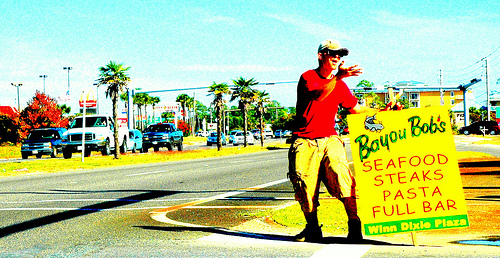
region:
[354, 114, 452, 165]
Green "Bayou Bob's" writing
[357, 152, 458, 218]
Red Seafood, Steaks, Pasta, Full bar writing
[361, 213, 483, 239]
Green and yellow "Winn Dixie Plaza" writing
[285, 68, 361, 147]
Red shirt man is wearing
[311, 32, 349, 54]
Baseball cap man is wearing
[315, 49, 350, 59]
Black sunglasses man is wearing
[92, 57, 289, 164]
Brown and green palm trees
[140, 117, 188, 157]
Blue truck on road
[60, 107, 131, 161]
White truck on road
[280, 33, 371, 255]
Man holding advertising sign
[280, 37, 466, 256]
a man holding a sign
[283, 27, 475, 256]
a man signing to passerbyers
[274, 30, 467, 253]
a man enticing customers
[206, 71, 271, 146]
palm trees behind the man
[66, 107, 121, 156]
a white van driving past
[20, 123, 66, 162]
a black suv driving on the street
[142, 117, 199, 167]
a black pick up truck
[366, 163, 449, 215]
red lettering on a yellow sign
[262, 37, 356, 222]
a man wearing a red shirt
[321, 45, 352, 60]
black sunglasses on a face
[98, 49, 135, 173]
A palm tree.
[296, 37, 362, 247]
A man wearing a red shirt.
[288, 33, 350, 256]
A man wearing a baseball hat.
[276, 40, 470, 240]
A man holding a sign.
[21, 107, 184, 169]
Cars driving on the road.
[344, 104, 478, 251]
A sign for a restaurant.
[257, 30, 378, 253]
A man standing on the road.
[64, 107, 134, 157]
A white pick up truck.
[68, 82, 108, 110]
A McDonald sign.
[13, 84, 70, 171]
A red tree.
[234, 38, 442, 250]
man holding sign on side of street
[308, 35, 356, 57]
brown cap on man's head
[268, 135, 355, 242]
tan cargo shorts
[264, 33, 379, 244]
man making hand gestures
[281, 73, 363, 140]
red t-shirt on man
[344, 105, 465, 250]
red and yellow sign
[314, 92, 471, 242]
lettering on sign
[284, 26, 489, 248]
man holding food sign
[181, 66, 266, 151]
group of palm trees in background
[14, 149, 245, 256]
asphalt road by man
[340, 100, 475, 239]
yellow sign on sidewalk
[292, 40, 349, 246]
man standing with yellow sign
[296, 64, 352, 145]
red shirt on man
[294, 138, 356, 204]
khaki shorts on man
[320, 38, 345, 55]
baseball cap on man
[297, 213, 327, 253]
shoes on the man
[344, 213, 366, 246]
shoes on the man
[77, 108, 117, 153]
vehicle on side of road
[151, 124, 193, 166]
vehicle on side of road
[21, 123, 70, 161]
vehicle on side of road